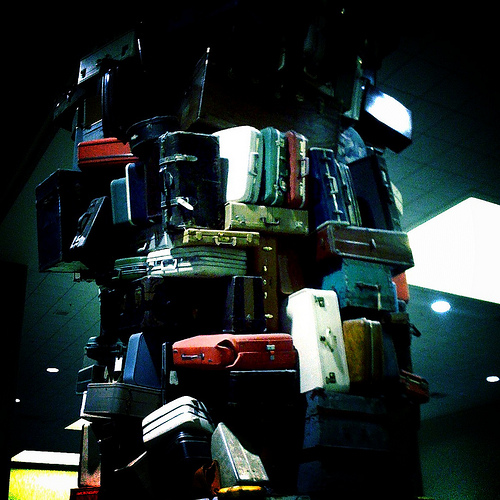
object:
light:
[428, 297, 450, 315]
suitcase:
[169, 331, 295, 367]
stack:
[137, 79, 420, 418]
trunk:
[32, 164, 87, 275]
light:
[403, 194, 500, 305]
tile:
[402, 162, 456, 191]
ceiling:
[0, 42, 499, 500]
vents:
[46, 364, 60, 375]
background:
[0, 2, 499, 498]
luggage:
[122, 330, 157, 393]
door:
[8, 446, 82, 466]